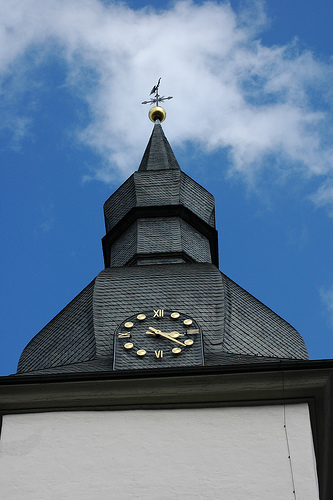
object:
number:
[171, 346, 180, 355]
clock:
[111, 307, 202, 374]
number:
[137, 312, 146, 319]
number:
[185, 328, 198, 336]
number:
[184, 336, 194, 348]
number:
[154, 349, 166, 359]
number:
[116, 330, 135, 339]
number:
[153, 306, 166, 318]